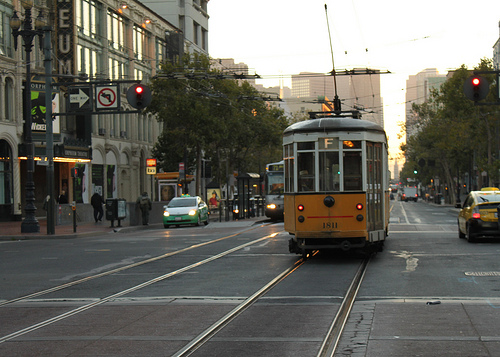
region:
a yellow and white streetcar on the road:
[270, 102, 402, 264]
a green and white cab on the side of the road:
[157, 192, 210, 234]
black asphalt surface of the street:
[214, 262, 251, 290]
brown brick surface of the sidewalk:
[79, 222, 98, 232]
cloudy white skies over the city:
[377, 19, 459, 61]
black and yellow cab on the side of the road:
[453, 177, 499, 242]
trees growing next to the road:
[396, 62, 496, 196]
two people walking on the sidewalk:
[78, 177, 160, 233]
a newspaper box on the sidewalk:
[100, 195, 132, 232]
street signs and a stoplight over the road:
[43, 74, 155, 125]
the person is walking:
[89, 188, 105, 225]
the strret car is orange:
[309, 199, 318, 210]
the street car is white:
[291, 131, 309, 143]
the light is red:
[353, 201, 363, 209]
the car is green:
[171, 207, 186, 214]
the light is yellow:
[187, 208, 198, 218]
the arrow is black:
[100, 91, 114, 103]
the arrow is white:
[73, 92, 88, 104]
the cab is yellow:
[481, 207, 493, 221]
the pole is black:
[23, 174, 36, 201]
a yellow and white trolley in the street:
[276, 107, 398, 260]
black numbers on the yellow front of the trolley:
[318, 220, 344, 234]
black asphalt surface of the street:
[296, 267, 337, 297]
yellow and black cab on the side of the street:
[453, 182, 498, 239]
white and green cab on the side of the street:
[153, 192, 213, 229]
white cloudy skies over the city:
[363, 0, 420, 60]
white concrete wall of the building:
[90, 123, 145, 168]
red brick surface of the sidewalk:
[73, 222, 96, 232]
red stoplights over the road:
[123, 68, 493, 114]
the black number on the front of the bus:
[321, 219, 339, 232]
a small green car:
[163, 196, 209, 223]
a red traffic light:
[134, 84, 144, 94]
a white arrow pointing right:
[66, 87, 90, 109]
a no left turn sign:
[95, 84, 118, 110]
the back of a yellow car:
[455, 187, 498, 244]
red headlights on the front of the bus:
[296, 204, 364, 208]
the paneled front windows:
[295, 140, 361, 191]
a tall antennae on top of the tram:
[322, 2, 343, 116]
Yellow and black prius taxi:
[455, 183, 499, 243]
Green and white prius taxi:
[160, 193, 210, 225]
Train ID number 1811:
[317, 220, 342, 230]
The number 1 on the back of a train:
[320, 220, 327, 230]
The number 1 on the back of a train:
[330, 220, 333, 230]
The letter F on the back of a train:
[315, 135, 336, 148]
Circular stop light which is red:
[125, 80, 155, 110]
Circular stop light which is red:
[460, 70, 490, 102]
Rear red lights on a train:
[295, 202, 367, 213]